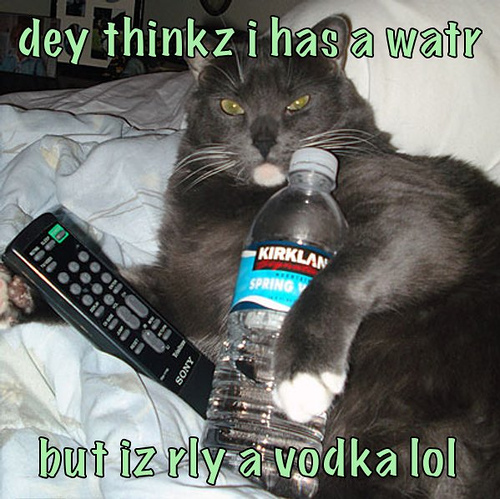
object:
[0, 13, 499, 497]
cat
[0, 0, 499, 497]
bed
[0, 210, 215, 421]
remote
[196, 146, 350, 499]
bottle